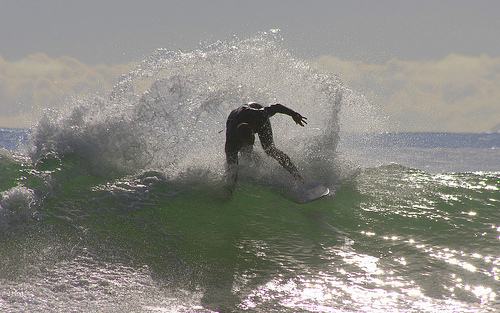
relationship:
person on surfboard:
[225, 99, 309, 192] [264, 170, 330, 205]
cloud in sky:
[393, 54, 500, 134] [0, 1, 499, 133]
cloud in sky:
[0, 52, 64, 121] [0, 1, 499, 133]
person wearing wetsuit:
[225, 99, 309, 192] [223, 102, 305, 183]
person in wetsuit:
[225, 99, 309, 192] [223, 102, 305, 183]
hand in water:
[223, 178, 238, 193] [8, 160, 499, 312]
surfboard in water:
[264, 170, 330, 205] [8, 160, 499, 312]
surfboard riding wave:
[264, 170, 330, 205] [139, 142, 349, 203]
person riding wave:
[225, 99, 309, 192] [139, 142, 349, 203]